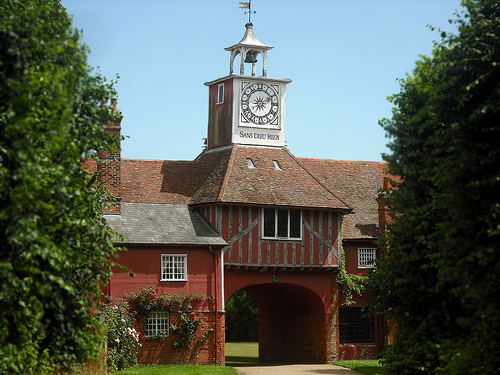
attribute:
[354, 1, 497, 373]
hedge — green, tall, clipped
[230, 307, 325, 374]
space — part 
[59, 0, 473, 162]
sky — clear blue 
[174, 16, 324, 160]
steeple — white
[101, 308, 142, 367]
rosebush — pink  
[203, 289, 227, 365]
wall — edge 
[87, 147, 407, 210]
roof — brown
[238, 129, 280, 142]
words — black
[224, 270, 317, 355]
tunnel — brick 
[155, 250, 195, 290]
window — white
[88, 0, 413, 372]
church — rustic, country-style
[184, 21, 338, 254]
tower — bell  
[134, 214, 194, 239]
roof — edge 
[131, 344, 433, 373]
lawn — manicured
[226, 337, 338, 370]
pathway — manicured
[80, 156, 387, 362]
building — top 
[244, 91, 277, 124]
face — clock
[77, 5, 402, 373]
building — top 